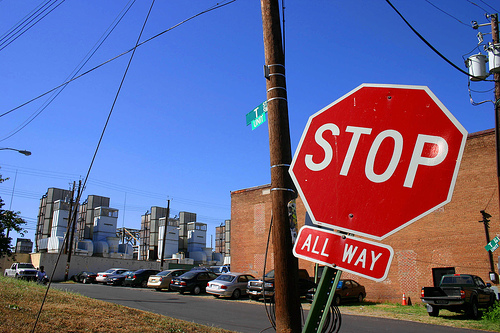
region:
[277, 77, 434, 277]
Red and white stop sign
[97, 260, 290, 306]
Cars parked in front of building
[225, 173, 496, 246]
Large brick building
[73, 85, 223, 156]
Cloudless blue sky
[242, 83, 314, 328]
Wooden post supporting a street sign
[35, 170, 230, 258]
Large storage containers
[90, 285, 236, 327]
Black cement paved road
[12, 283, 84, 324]
Brown grass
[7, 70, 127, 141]
Telephone wires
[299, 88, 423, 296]
Stop sign is leaning sideways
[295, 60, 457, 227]
A red and white stop sign.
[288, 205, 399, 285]
A red and white sign that says all way.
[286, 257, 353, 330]
The stop sign is on a leaning post.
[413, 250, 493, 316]
A pickup truck across the street.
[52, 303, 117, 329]
The grass is brown.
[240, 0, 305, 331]
The power pole is brown.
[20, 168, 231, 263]
Buildings in the distance.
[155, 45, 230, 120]
The sky is blue.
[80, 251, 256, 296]
Cars parked next to the street.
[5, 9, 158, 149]
Power lines are connected to the pole.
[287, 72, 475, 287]
red and white sign on a post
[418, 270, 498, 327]
truck parked on grass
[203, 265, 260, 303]
car parked on grass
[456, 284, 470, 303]
rear taillight on a truck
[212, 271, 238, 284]
rear window on a vehicle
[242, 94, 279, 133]
street sign on a pole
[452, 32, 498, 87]
electric transformers on a pole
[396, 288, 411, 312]
traffic cone on grass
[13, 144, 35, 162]
street light on a pole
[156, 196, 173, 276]
utility pole in the ground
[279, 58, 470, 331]
a tipped four way stop sign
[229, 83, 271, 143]
green street signs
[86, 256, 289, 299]
cars parked off the street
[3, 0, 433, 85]
deep blue cloudless sky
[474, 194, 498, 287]
street sins in the shadow of a power pole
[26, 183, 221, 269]
tall city buildings set before a bridge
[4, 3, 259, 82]
numerous power lines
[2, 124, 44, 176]
street light over a road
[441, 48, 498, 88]
powerline transformers mounted on pole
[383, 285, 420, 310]
an orange traffic pylon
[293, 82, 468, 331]
red stop sign on green metal post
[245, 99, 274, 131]
green street sign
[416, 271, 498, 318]
parked black pickup truck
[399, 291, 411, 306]
orange traffic cone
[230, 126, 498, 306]
red brick building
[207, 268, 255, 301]
silver car parked near building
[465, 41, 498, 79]
two grey electrical transformers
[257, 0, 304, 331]
wood electrical pole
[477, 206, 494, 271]
shadow of electrical pole on red brick wall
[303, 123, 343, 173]
letter S on stop sign